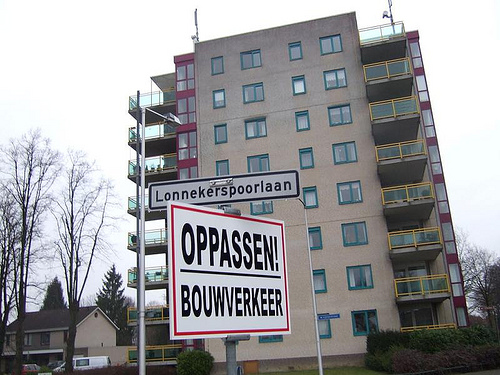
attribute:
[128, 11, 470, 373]
building — tall, off white, tan, small, apartment building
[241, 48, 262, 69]
window — blue framed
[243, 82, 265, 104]
window — blue framed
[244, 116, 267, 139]
window — blue framed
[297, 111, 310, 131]
window — blue framed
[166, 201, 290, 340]
sign — white, black, red, street sign, square, Oppassen! Bouwverkeer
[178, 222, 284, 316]
letters — black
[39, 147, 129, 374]
tree — bare, tall, leafless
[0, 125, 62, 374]
tree — bare, tall, leafless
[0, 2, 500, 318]
sky — white, clear, cloudless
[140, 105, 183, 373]
light pole — tall, silver, metal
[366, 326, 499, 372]
bush — green, short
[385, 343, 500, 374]
bush — purple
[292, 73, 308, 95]
trim — blue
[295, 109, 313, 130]
trim — blue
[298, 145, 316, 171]
trim — blue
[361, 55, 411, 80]
trim — yellow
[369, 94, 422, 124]
trim — yellow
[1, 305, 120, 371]
house — tan, brown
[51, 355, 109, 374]
van — white, parked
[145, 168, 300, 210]
sign — blue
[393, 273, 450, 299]
guard rail — glass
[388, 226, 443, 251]
guard rail — glass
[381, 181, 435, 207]
guard rail — glass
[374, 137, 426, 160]
guard rail — glass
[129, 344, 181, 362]
guard rail — glass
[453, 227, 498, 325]
tree — leafless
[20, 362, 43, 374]
car — parked